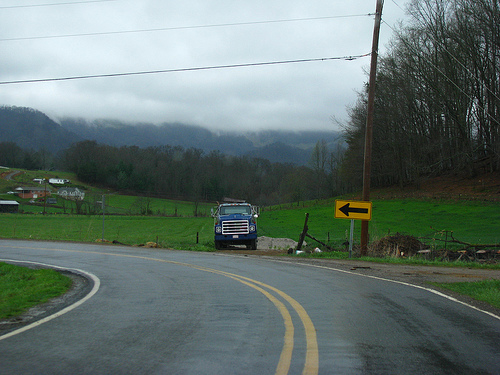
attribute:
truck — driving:
[201, 191, 282, 264]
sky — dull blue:
[0, 0, 460, 131]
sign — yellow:
[321, 180, 386, 238]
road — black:
[130, 300, 154, 347]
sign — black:
[325, 187, 403, 233]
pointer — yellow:
[335, 194, 374, 221]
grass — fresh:
[412, 189, 463, 222]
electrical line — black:
[7, 49, 337, 81]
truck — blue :
[208, 195, 261, 250]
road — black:
[132, 270, 249, 370]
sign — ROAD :
[334, 200, 373, 222]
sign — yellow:
[329, 197, 374, 222]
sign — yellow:
[321, 175, 395, 237]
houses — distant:
[1, 198, 18, 215]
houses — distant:
[10, 183, 55, 199]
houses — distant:
[55, 185, 84, 200]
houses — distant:
[34, 174, 71, 187]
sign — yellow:
[328, 197, 388, 229]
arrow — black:
[334, 202, 369, 220]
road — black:
[0, 232, 498, 373]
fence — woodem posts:
[291, 210, 345, 262]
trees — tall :
[334, 71, 496, 218]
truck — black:
[200, 182, 272, 254]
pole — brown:
[361, 9, 376, 260]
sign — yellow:
[333, 195, 370, 226]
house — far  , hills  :
[35, 175, 71, 186]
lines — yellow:
[251, 268, 297, 371]